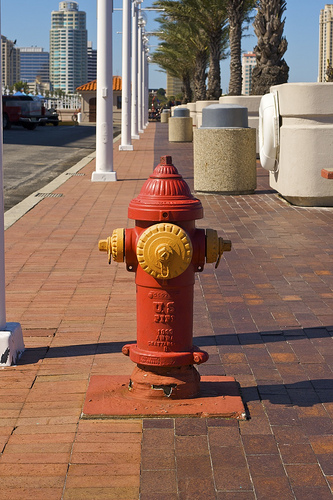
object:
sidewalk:
[0, 121, 333, 500]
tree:
[203, 0, 261, 97]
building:
[47, 0, 89, 96]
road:
[0, 121, 122, 216]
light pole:
[89, 0, 119, 185]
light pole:
[118, 1, 134, 152]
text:
[153, 299, 176, 323]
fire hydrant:
[80, 151, 248, 421]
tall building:
[241, 49, 258, 96]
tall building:
[316, 3, 331, 84]